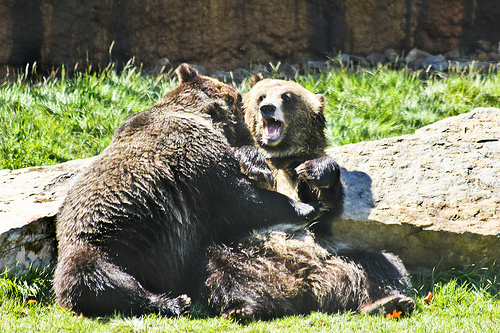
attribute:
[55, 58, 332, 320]
bear — assertive-looking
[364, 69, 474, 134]
green grass — patch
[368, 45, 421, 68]
assorted rocks — distant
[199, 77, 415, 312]
bear — angry-looking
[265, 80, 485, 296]
rock — large, slab